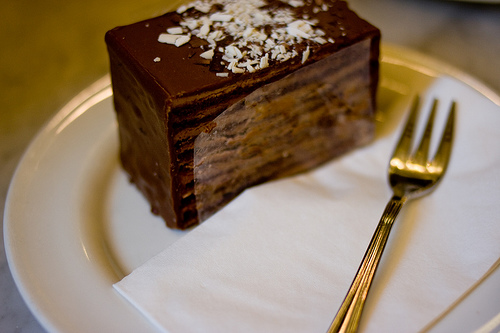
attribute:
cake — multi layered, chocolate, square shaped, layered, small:
[105, 0, 381, 226]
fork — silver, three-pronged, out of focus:
[329, 94, 459, 331]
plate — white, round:
[4, 44, 499, 329]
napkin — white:
[115, 75, 499, 330]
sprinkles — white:
[155, 2, 332, 76]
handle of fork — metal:
[326, 201, 400, 332]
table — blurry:
[1, 1, 497, 332]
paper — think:
[195, 39, 372, 229]